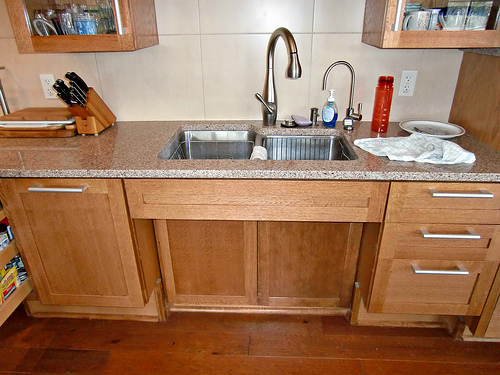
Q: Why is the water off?
A: It isn't being used.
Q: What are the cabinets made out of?
A: Wood.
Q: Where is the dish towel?
A: On the counter.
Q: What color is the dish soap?
A: Blue.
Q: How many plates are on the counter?
A: One.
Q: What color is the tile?
A: Beige.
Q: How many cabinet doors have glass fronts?
A: Two.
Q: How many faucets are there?
A: Two.